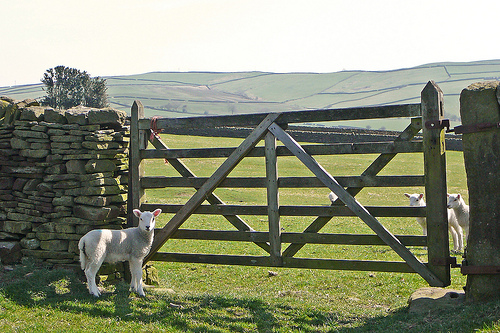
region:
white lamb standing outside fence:
[68, 208, 173, 312]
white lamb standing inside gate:
[398, 187, 447, 258]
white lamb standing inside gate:
[429, 191, 481, 268]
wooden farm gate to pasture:
[119, 109, 466, 289]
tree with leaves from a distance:
[40, 51, 108, 111]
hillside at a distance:
[158, 56, 428, 142]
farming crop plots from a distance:
[167, 75, 443, 119]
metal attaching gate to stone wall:
[414, 109, 498, 145]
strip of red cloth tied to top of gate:
[140, 111, 187, 156]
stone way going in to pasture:
[13, 102, 152, 285]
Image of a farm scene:
[1, 67, 494, 331]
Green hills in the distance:
[113, 57, 498, 99]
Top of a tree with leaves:
[38, 64, 110, 104]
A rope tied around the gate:
[147, 114, 159, 132]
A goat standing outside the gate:
[76, 208, 163, 295]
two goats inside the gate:
[404, 186, 463, 262]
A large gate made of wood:
[163, 110, 448, 262]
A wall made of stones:
[0, 103, 78, 267]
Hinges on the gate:
[440, 118, 467, 278]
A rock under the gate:
[403, 283, 461, 316]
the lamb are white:
[49, 167, 492, 329]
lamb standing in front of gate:
[47, 183, 172, 298]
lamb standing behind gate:
[340, 158, 498, 283]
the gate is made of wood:
[124, 85, 491, 305]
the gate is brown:
[114, 85, 491, 305]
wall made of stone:
[1, 88, 144, 286]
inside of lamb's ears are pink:
[114, 194, 204, 242]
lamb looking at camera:
[126, 197, 181, 249]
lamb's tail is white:
[57, 223, 98, 270]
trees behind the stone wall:
[24, 58, 132, 118]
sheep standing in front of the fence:
[75, 208, 161, 296]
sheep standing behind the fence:
[328, 183, 468, 256]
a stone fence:
[0, 84, 498, 298]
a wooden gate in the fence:
[122, 77, 451, 286]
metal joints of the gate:
[424, 114, 498, 274]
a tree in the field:
[39, 65, 109, 111]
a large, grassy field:
[0, 113, 498, 330]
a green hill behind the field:
[0, 56, 499, 132]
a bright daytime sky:
[0, 0, 499, 86]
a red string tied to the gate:
[147, 113, 162, 141]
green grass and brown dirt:
[194, 283, 295, 314]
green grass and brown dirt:
[300, 283, 368, 329]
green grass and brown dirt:
[36, 292, 75, 317]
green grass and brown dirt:
[200, 270, 325, 305]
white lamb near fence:
[61, 200, 178, 297]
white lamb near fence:
[399, 185, 422, 214]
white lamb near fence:
[443, 191, 468, 226]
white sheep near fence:
[64, 200, 167, 289]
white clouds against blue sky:
[108, 15, 217, 47]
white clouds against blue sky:
[241, 18, 364, 63]